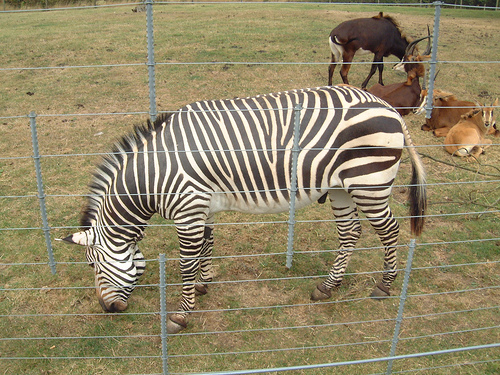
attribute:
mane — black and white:
[61, 101, 164, 199]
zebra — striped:
[74, 73, 428, 304]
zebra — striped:
[74, 79, 428, 324]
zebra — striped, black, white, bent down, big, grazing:
[55, 81, 432, 334]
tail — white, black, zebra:
[402, 123, 429, 242]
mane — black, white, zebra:
[70, 110, 170, 248]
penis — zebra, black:
[315, 189, 329, 209]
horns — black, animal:
[408, 25, 433, 60]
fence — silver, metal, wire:
[9, 20, 485, 367]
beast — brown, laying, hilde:
[380, 36, 439, 117]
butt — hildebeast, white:
[326, 29, 351, 65]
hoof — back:
[309, 279, 339, 305]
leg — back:
[306, 197, 364, 302]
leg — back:
[352, 184, 400, 297]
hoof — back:
[368, 283, 392, 298]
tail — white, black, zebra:
[401, 121, 431, 236]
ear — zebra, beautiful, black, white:
[60, 225, 100, 254]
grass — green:
[75, 263, 165, 331]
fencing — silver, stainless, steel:
[14, 9, 471, 365]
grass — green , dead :
[33, 69, 125, 114]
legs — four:
[164, 189, 406, 329]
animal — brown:
[444, 113, 484, 155]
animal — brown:
[415, 85, 471, 125]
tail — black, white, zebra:
[404, 129, 429, 237]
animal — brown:
[319, 11, 428, 89]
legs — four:
[326, 54, 387, 86]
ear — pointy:
[53, 226, 95, 249]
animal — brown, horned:
[323, 14, 434, 84]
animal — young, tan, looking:
[443, 94, 475, 174]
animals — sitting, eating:
[324, 10, 481, 161]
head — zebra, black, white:
[49, 225, 146, 314]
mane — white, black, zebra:
[74, 107, 176, 235]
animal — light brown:
[441, 101, 484, 158]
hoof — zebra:
[160, 313, 185, 332]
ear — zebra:
[51, 220, 95, 250]